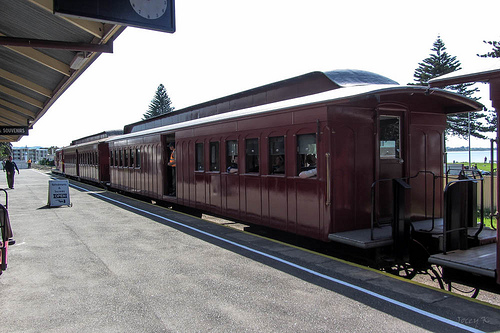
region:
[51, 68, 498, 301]
The train is long.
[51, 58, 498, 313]
The train is maroon.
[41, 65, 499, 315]
The train is at the train station.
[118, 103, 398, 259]
A man in a safety vest is standing on the train.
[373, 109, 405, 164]
The window is rectangular.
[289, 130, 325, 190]
The window is rectangular.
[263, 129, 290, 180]
The window is rectangular.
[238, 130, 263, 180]
The window is rectangular.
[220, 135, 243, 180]
The window is rectangular.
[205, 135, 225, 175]
The window is rectangular.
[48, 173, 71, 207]
white sign on the ground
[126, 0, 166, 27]
clock hanging at station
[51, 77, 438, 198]
burgundy train at station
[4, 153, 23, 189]
man walking at station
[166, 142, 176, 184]
worker on the train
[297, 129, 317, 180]
window on side of train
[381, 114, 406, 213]
back door of the train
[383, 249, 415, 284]
black wheel on the train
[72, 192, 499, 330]
white lines painted on ground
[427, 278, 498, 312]
yellow line painted on curb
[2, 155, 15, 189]
man walking on sidewalk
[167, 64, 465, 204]
red train car at train station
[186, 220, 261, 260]
white line at train station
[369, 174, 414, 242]
black metal safety rails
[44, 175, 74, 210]
black and white sign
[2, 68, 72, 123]
gold and black awning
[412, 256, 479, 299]
black cable car hookups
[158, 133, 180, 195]
man in orange jacket at door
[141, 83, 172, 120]
pine tree over red train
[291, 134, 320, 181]
persons arm out of red train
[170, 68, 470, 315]
Train on the tracks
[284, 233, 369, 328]
Shadow on the pavement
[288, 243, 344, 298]
White paint on the pavement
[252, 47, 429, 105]
Roof on the train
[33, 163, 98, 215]
Sign beside the train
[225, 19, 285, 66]
Sky is full of clouds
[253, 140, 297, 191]
Window on side of train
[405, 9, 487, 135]
Tree in the background behind train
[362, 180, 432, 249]
Metal on the train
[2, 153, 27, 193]
Person walking on the pavement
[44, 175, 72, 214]
sign next to the train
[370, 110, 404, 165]
window on the train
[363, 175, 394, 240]
railing on the train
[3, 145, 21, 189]
person walking on the sidewalk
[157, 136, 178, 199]
person in the doorway of the train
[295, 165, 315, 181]
arm out the window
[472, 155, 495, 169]
person by the water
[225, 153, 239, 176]
person looking out the window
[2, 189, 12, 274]
luggage rack on the sidewalk